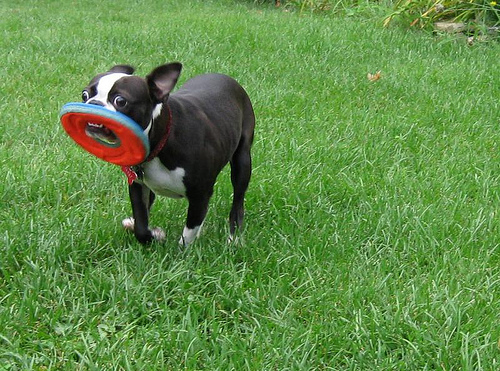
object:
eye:
[113, 93, 126, 110]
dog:
[80, 60, 255, 249]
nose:
[82, 95, 100, 109]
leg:
[176, 172, 211, 246]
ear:
[144, 61, 182, 105]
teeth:
[88, 121, 110, 129]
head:
[78, 62, 181, 145]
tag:
[118, 166, 137, 183]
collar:
[144, 102, 176, 161]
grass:
[0, 0, 499, 370]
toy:
[56, 102, 152, 164]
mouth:
[84, 121, 105, 135]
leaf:
[362, 71, 384, 86]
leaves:
[372, 0, 498, 30]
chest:
[141, 156, 188, 200]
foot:
[176, 229, 195, 247]